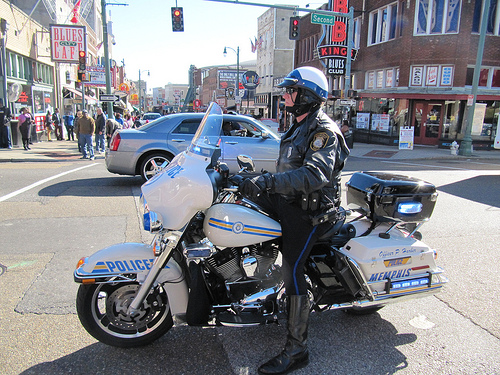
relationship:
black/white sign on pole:
[101, 95, 119, 101] [95, 0, 114, 121]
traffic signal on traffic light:
[289, 17, 299, 26] [283, 7, 305, 40]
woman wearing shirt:
[17, 104, 34, 152] [15, 112, 30, 128]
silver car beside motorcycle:
[103, 112, 311, 192] [68, 94, 450, 355]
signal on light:
[170, 7, 182, 20] [168, 4, 185, 32]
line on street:
[2, 160, 101, 201] [0, 154, 498, 373]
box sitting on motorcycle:
[376, 170, 446, 211] [261, 63, 346, 255]